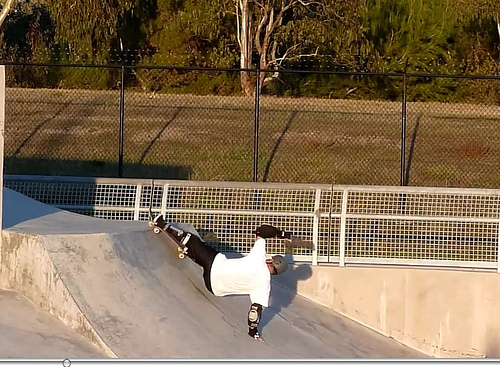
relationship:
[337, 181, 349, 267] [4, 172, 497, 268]
pole in fence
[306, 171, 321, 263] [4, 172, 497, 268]
pole in fence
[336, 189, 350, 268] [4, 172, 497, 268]
pole in fence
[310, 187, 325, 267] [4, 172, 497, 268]
pole in fence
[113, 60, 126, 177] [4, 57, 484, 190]
pole in fence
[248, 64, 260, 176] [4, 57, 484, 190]
pole in fence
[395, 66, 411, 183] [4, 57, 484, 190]
pole in fence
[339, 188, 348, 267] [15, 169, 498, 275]
pole in fence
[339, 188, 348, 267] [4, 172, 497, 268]
pole in fence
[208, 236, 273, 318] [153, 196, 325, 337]
shirt on man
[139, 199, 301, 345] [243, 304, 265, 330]
man has arm pad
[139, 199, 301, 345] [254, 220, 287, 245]
man has arm pad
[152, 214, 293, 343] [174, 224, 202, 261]
man has knee pad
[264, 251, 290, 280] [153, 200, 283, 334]
helmet on man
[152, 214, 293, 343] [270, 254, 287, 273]
man wearing helmet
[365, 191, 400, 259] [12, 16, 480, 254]
fence in background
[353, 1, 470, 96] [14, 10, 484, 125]
tree in distance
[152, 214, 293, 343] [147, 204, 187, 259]
man on a skateboard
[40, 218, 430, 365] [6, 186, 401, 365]
ramp made of concrete